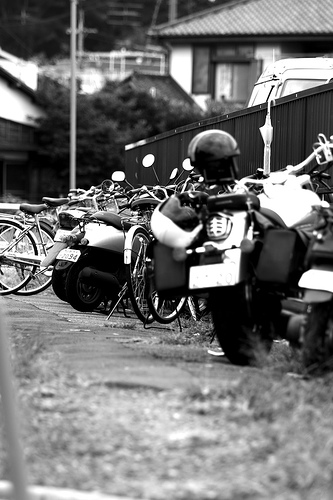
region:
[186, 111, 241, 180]
black helmet near bike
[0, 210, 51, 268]
black wheels on bikes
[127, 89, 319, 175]
black rails behind bikes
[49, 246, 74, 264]
license plate on motorcycle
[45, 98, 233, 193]
green bushes behind bikes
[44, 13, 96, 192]
pole in front of bushes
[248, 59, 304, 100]
van is parked behind fence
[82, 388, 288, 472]
grass in front of bikes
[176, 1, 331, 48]
textured roof on building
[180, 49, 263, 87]
light colored building behind van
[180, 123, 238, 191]
the helmet is black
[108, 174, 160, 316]
the bike is parked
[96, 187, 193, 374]
the bike is parked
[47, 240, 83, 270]
plate number ends in 94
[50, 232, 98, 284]
plate number ends in 94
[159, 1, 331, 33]
tile roof of building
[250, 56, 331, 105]
roof and windows of vehicle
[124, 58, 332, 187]
wall in front of vehicles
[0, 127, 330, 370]
cluster of parked bikes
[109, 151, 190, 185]
mirrors on top of poles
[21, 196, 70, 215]
two seats of bicycles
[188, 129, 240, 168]
helmet on top of bike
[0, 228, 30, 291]
spokes in bike wheel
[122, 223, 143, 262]
fender on bike tire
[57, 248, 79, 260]
number on license plate